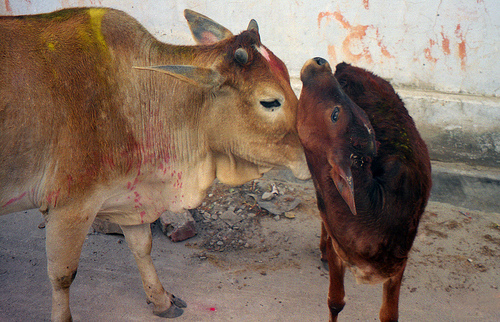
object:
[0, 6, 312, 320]
cow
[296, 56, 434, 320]
calf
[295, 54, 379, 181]
head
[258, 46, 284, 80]
stain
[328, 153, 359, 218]
ear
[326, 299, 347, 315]
hoof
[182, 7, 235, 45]
ear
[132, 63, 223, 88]
ear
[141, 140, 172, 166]
stains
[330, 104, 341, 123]
eye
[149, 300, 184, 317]
hoof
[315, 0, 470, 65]
graffiti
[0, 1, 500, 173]
wall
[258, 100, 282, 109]
eye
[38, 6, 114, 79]
paint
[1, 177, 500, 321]
ground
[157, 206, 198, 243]
brick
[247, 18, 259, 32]
horn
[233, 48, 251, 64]
horn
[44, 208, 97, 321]
leg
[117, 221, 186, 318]
leg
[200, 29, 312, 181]
head